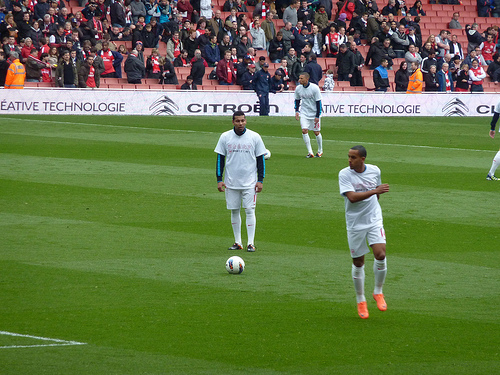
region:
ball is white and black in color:
[225, 252, 270, 288]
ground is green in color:
[77, 158, 130, 238]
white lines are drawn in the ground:
[18, 311, 113, 371]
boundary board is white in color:
[14, 92, 201, 124]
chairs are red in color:
[105, 75, 142, 90]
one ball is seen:
[208, 230, 261, 319]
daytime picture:
[53, 46, 441, 286]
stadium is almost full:
[30, 11, 473, 87]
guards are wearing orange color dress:
[5, 58, 27, 93]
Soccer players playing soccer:
[207, 73, 402, 313]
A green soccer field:
[1, 113, 219, 374]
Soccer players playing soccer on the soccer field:
[0, 75, 498, 368]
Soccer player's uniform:
[207, 134, 269, 254]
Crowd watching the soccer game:
[1, 3, 496, 91]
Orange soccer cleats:
[351, 288, 396, 321]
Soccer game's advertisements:
[0, 91, 499, 116]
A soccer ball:
[221, 254, 251, 276]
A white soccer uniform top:
[338, 166, 390, 231]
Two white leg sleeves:
[228, 208, 258, 246]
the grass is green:
[90, 201, 194, 280]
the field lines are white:
[18, 318, 78, 363]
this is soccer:
[13, 21, 496, 374]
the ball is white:
[174, 242, 280, 319]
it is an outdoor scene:
[1, 42, 493, 374]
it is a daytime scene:
[15, 47, 460, 352]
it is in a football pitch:
[2, 40, 487, 370]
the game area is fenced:
[8, 54, 478, 371]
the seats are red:
[133, 79, 147, 87]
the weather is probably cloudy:
[8, 45, 457, 355]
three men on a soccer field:
[211, 71, 416, 323]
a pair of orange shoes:
[353, 287, 393, 319]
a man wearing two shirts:
[207, 113, 278, 200]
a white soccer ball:
[219, 253, 253, 279]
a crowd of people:
[8, 1, 470, 84]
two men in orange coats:
[1, 47, 433, 92]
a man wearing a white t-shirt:
[333, 141, 390, 224]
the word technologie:
[41, 99, 134, 116]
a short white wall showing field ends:
[0, 86, 498, 128]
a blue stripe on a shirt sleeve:
[212, 147, 227, 183]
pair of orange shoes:
[353, 290, 387, 322]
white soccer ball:
[219, 253, 250, 276]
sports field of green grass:
[3, 116, 498, 368]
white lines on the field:
[4, 312, 94, 374]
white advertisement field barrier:
[0, 88, 499, 113]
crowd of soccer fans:
[0, 2, 425, 86]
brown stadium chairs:
[411, 2, 494, 44]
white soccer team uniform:
[217, 125, 264, 214]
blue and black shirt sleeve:
[255, 150, 272, 187]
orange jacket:
[401, 62, 424, 97]